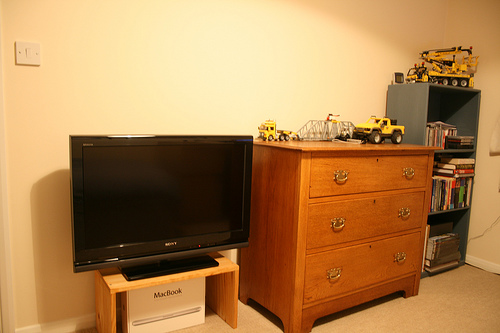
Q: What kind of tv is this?
A: Sony.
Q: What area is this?
A: A room.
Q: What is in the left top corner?
A: A light switch.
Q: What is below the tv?
A: Macbook box.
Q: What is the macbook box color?
A: White.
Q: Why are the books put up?
A: To keep organized.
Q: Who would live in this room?
A: A kid.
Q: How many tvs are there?
A: One.